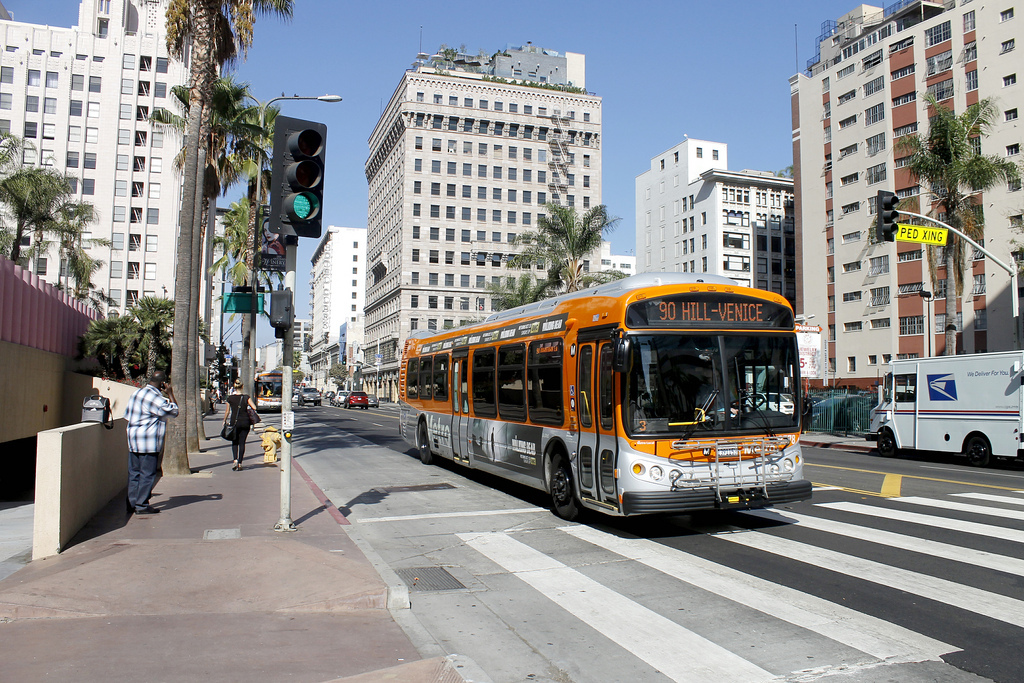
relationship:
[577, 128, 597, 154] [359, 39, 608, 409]
window on building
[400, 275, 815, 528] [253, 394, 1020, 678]
bus on a street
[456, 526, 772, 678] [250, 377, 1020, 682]
line on street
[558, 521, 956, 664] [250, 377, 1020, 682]
line on street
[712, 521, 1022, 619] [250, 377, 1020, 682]
line on street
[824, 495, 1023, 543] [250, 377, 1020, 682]
line on street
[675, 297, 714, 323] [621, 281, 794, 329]
word on a board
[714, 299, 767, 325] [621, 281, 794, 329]
word on a board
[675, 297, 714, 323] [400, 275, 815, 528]
word on a bus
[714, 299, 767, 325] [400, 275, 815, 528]
word on a bus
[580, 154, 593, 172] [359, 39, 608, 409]
window on building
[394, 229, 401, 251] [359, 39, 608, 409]
window on building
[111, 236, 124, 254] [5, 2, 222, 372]
window on building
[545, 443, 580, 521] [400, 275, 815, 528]
tire on front of bus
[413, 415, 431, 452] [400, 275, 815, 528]
tire on back of bus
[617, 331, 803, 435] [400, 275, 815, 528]
windshield of bus